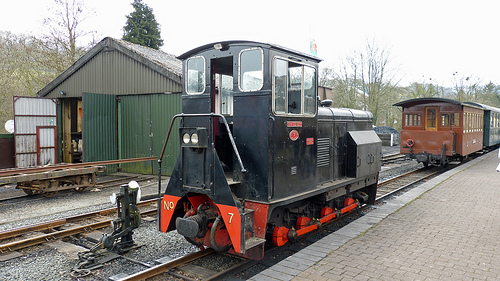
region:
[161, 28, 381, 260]
a train on the railway track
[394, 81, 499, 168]
a train on the railway track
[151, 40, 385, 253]
a train is orange and black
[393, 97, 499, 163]
a train is brown in color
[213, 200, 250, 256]
a number on the train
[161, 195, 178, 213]
letters on the train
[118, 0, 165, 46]
a tree in the background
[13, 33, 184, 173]
an iron sheet structure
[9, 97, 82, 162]
the door is open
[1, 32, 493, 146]
trees in the photo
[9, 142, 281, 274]
the rails are rusty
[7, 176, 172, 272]
the rails are rusty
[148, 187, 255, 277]
Bottom of train has orange on it.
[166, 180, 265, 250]
Number 7 written in white writing.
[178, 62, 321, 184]
Train car is black in color.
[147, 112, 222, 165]
Lights on train.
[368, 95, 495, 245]
Red train car on tracks.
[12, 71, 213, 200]
Green building near train.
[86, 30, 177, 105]
Gray roof on building.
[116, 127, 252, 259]
Train on tracks.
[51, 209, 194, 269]
Gravel around and under tracks.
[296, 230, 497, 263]
Brick platform area near train.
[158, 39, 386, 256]
a train on the railway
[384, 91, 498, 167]
a train on the railway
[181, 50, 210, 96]
a window on the train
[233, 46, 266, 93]
a window on the train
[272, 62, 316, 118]
a window on the train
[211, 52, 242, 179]
a door on the train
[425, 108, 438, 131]
a window on the train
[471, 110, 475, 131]
a window on the train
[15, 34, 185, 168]
an iron sheet house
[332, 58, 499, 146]
green trees in the background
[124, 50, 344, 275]
the train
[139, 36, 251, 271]
the train